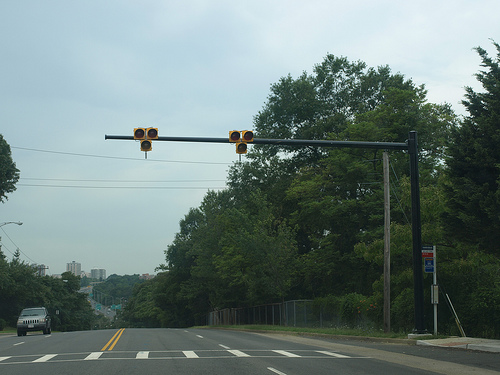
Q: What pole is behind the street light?
A: Powerline pole.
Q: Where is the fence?
A: Between the trees and road.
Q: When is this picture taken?
A: Day time.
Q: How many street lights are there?
A: Two.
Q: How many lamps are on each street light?
A: Three.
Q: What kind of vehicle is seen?
A: SUV.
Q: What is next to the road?
A: Trees.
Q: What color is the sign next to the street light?
A: Blue and red.